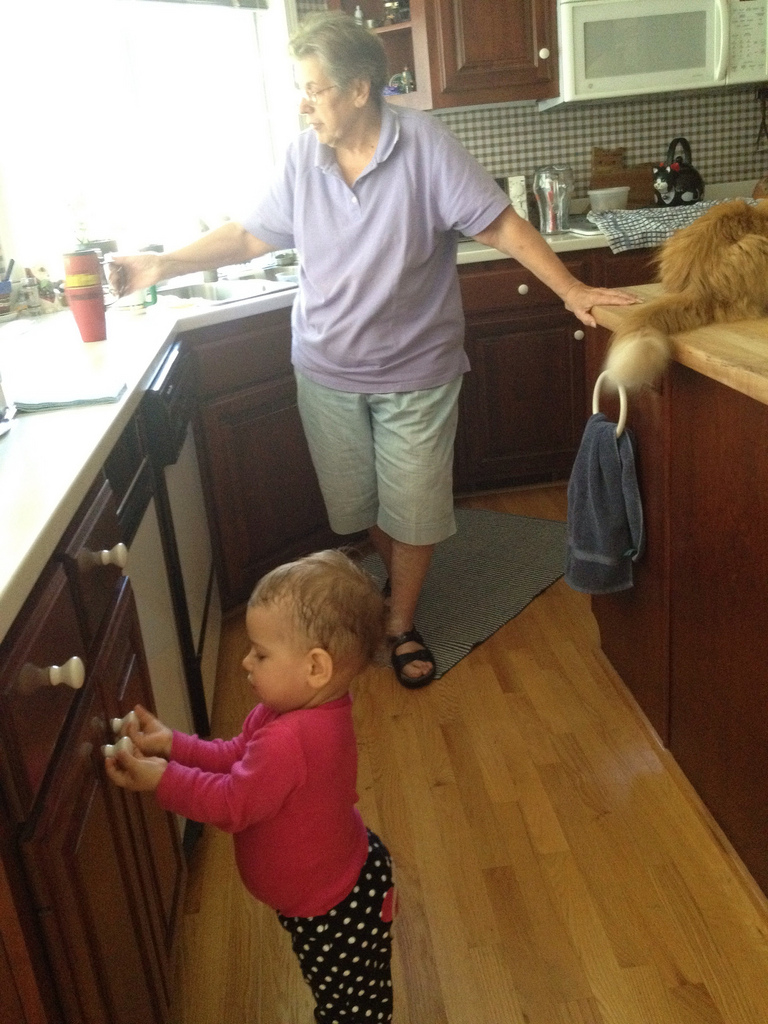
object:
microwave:
[555, 1, 768, 108]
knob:
[49, 655, 86, 692]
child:
[103, 540, 401, 1024]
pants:
[275, 827, 398, 1019]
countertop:
[575, 269, 768, 436]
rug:
[351, 501, 570, 681]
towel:
[561, 410, 647, 597]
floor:
[176, 468, 768, 1020]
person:
[105, 14, 639, 690]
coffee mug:
[58, 250, 108, 344]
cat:
[608, 198, 767, 347]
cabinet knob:
[104, 735, 135, 762]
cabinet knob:
[100, 539, 130, 570]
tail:
[599, 282, 712, 395]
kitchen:
[0, 22, 762, 1018]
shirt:
[158, 692, 373, 917]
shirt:
[236, 100, 518, 398]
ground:
[387, 731, 606, 846]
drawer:
[53, 478, 129, 654]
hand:
[104, 737, 172, 797]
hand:
[116, 703, 175, 758]